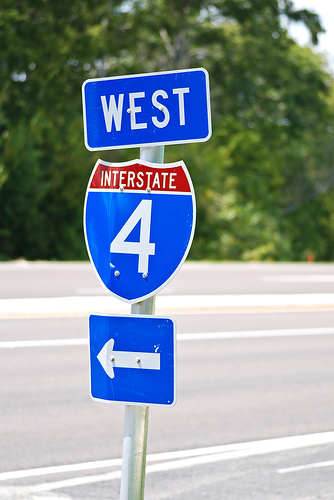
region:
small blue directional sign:
[71, 62, 222, 150]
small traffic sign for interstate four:
[76, 154, 202, 309]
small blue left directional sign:
[74, 308, 185, 414]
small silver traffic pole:
[107, 138, 169, 495]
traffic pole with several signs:
[61, 60, 224, 452]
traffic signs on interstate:
[6, 25, 328, 458]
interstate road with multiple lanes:
[2, 249, 332, 499]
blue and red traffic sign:
[67, 151, 209, 309]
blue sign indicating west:
[67, 59, 224, 154]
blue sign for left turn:
[66, 306, 190, 417]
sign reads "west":
[60, 75, 230, 141]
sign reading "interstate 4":
[78, 152, 216, 302]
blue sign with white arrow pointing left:
[80, 310, 207, 409]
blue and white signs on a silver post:
[57, 63, 229, 437]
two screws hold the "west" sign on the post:
[74, 76, 244, 148]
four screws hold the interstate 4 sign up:
[82, 154, 198, 302]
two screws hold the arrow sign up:
[74, 311, 180, 415]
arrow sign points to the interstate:
[76, 310, 201, 426]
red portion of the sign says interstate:
[75, 155, 214, 201]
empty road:
[201, 313, 264, 415]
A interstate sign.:
[65, 53, 187, 496]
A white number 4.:
[109, 193, 159, 273]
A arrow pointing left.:
[90, 314, 176, 404]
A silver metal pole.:
[113, 407, 149, 496]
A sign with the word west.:
[84, 78, 214, 146]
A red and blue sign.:
[65, 154, 201, 297]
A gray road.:
[12, 264, 330, 495]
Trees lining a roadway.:
[1, 71, 332, 262]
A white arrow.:
[95, 335, 162, 383]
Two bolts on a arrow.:
[106, 354, 142, 363]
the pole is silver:
[73, 419, 158, 491]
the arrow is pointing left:
[60, 310, 189, 419]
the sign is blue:
[66, 307, 183, 426]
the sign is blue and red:
[52, 150, 204, 306]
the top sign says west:
[47, 55, 224, 152]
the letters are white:
[94, 83, 196, 135]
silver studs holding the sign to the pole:
[101, 354, 146, 367]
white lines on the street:
[171, 411, 327, 475]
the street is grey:
[200, 332, 300, 436]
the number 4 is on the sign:
[103, 196, 165, 277]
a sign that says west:
[51, 57, 240, 158]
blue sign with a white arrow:
[65, 310, 198, 435]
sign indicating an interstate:
[65, 148, 225, 322]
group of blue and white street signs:
[33, 53, 264, 448]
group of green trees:
[8, 10, 328, 263]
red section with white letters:
[82, 146, 198, 197]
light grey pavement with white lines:
[14, 263, 325, 485]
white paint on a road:
[80, 418, 319, 488]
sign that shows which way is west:
[46, 71, 272, 412]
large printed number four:
[81, 188, 203, 293]